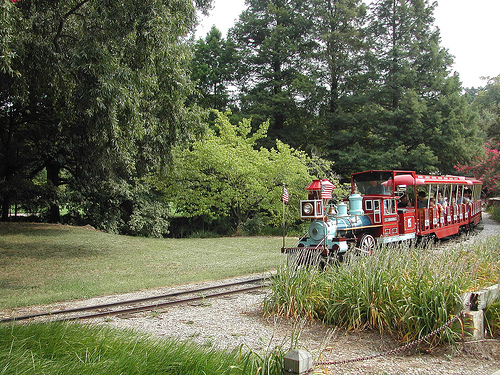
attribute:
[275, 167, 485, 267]
train —  miniature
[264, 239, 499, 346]
grass — tall 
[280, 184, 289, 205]
american flag —  two,  american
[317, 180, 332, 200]
american flag —  american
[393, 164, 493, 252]
carts — red 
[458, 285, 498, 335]
post —  two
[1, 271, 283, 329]
train tracks — small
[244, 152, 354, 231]
flags — small 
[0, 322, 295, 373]
grass — tall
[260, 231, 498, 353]
grass — tall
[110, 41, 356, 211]
trees — green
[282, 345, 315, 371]
post — wooden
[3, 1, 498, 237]
leaves — green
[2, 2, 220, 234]
tree — big